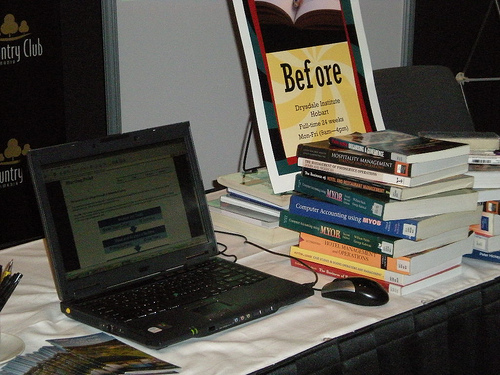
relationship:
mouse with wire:
[319, 273, 392, 309] [210, 225, 328, 296]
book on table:
[327, 125, 472, 166] [2, 128, 499, 375]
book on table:
[297, 163, 477, 203] [2, 128, 499, 375]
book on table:
[286, 190, 485, 243] [2, 128, 499, 375]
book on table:
[275, 206, 473, 262] [2, 128, 499, 375]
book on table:
[284, 242, 465, 287] [2, 128, 499, 375]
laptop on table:
[21, 117, 318, 351] [2, 128, 499, 375]